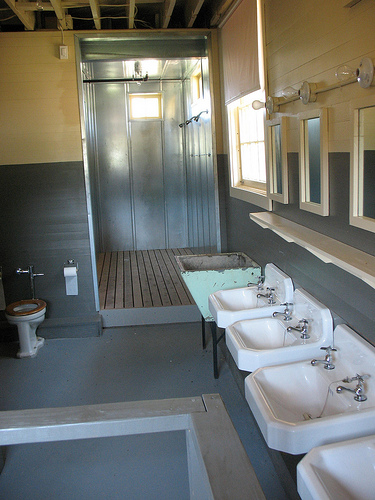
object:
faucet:
[336, 373, 366, 402]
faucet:
[310, 346, 337, 370]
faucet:
[287, 317, 310, 338]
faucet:
[257, 287, 276, 304]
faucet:
[246, 276, 264, 292]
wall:
[216, 2, 374, 346]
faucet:
[272, 302, 293, 322]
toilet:
[4, 299, 47, 359]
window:
[223, 0, 271, 212]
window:
[129, 93, 163, 119]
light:
[252, 100, 265, 111]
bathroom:
[0, 0, 374, 495]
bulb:
[335, 65, 357, 82]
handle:
[17, 268, 44, 278]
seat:
[5, 299, 47, 316]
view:
[227, 49, 266, 187]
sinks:
[208, 263, 374, 499]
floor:
[0, 321, 298, 499]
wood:
[97, 246, 218, 309]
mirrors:
[264, 94, 374, 234]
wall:
[0, 43, 96, 319]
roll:
[63, 266, 78, 295]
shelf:
[248, 211, 375, 289]